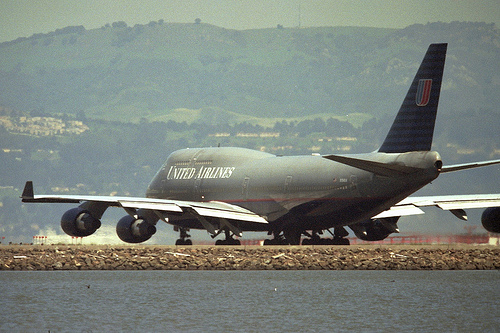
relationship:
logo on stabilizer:
[415, 78, 432, 106] [376, 42, 449, 153]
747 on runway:
[20, 42, 498, 245] [1, 241, 498, 246]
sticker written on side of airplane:
[167, 166, 235, 181] [18, 42, 500, 245]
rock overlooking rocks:
[0, 248, 500, 271] [24, 258, 494, 273]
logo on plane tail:
[413, 75, 434, 107] [379, 36, 446, 151]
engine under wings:
[115, 213, 156, 244] [43, 175, 244, 215]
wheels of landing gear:
[173, 235, 350, 245] [62, 208, 171, 246]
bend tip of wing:
[19, 180, 45, 203] [18, 178, 268, 226]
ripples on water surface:
[64, 289, 190, 333] [3, 250, 486, 333]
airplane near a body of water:
[18, 42, 500, 245] [52, 263, 419, 330]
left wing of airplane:
[64, 111, 294, 268] [18, 42, 500, 245]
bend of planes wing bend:
[19, 180, 45, 203] [10, 145, 53, 254]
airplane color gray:
[18, 42, 500, 245] [128, 129, 419, 219]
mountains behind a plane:
[60, 15, 341, 131] [62, 134, 435, 253]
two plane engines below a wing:
[91, 200, 279, 250] [18, 178, 268, 226]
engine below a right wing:
[353, 202, 419, 254] [52, 179, 223, 253]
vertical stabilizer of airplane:
[351, 50, 466, 167] [18, 42, 500, 245]